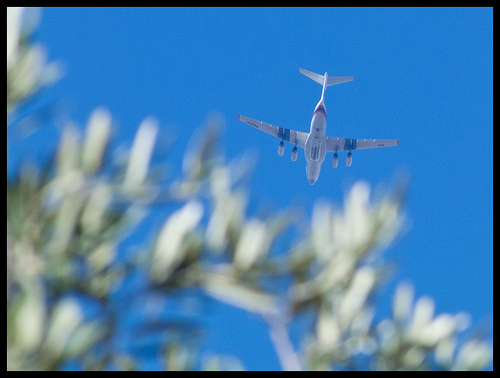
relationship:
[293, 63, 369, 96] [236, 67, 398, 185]
wing of jet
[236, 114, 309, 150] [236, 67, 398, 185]
wings of jet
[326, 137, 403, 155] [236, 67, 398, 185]
wing of jet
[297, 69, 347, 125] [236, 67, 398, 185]
back of jet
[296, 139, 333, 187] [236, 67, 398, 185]
front of jet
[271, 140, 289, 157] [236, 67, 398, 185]
fan of jet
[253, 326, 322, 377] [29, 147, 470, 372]
branches of tree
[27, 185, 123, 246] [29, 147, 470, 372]
leaves of tree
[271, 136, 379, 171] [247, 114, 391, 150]
engines on wings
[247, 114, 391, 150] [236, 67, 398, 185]
wings of jet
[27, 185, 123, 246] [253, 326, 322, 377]
leaves on branches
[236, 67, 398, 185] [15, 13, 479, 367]
jet in sky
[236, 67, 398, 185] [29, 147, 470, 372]
jet over tree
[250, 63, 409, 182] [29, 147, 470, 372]
jet over tree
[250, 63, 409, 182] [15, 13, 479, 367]
jet in sky